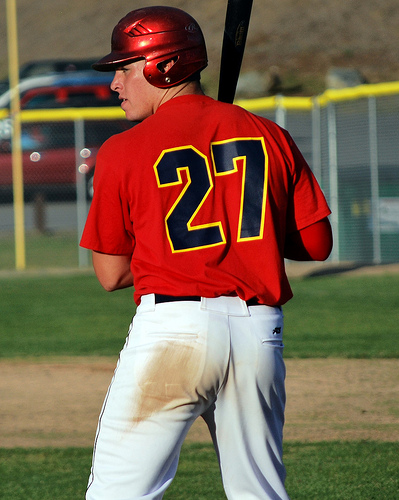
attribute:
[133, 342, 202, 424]
stains — dirt 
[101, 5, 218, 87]
helmet — red 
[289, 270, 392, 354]
grass — green 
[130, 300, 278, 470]
pants — white 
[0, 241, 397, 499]
grass — green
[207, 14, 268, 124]
bat — black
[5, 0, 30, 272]
pole — yellow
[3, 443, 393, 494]
grass — green